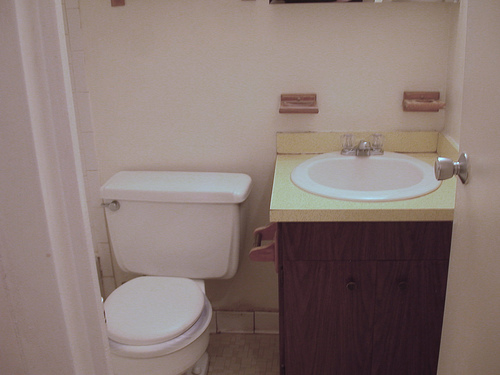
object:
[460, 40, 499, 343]
door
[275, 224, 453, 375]
cabinet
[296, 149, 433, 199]
sink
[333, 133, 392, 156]
faucet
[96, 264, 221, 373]
toliet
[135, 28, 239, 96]
wall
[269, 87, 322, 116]
soap holder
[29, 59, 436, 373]
toliet set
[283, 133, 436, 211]
sink fixture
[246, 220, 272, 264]
toliet roll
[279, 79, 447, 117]
soapdishes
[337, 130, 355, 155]
coldwater knob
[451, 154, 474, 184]
handle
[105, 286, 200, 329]
lid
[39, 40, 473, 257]
bathroom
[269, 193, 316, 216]
counter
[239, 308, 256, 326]
tile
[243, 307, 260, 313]
mold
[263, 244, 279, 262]
holder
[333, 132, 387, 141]
handles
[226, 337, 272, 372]
floor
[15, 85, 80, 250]
shower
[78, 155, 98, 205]
white tile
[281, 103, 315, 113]
tray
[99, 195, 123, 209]
flush handle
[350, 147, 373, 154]
fixture